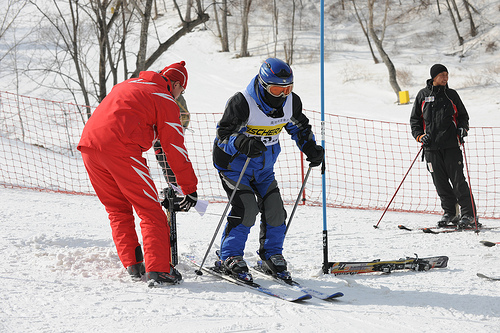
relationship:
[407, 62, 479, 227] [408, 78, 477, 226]
man wearing clothing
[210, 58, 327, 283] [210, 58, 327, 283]
man in man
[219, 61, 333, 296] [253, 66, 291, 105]
man in helmet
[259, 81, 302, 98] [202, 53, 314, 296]
goggles in man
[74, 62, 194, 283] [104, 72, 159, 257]
man in suit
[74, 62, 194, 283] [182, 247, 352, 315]
man on skis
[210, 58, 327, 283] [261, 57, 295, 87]
man wearing helmet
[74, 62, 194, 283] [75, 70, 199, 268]
man wearing outfit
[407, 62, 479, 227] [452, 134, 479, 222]
man holding ski pole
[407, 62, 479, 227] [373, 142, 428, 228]
man holding poles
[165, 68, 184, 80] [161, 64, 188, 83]
stripe on hat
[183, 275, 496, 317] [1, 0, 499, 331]
shadows on snow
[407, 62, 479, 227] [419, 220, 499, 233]
man wearing ski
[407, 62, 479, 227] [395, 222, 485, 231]
man wearing ski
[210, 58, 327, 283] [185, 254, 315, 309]
man wearing ski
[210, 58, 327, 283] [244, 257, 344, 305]
man wearing ski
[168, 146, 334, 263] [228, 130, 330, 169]
poles in skier's hand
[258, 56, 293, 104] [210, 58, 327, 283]
helmet on man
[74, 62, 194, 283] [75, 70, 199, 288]
man in outfit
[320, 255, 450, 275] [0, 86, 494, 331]
ski in snow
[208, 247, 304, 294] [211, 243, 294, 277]
boots on skier's feet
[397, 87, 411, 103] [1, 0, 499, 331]
object on snow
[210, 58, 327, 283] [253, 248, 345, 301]
man on ski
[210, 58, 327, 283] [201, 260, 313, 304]
man on ski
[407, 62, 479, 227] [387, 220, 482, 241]
man on skis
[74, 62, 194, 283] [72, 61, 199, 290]
man wearing gear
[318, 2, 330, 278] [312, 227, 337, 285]
blue pole with base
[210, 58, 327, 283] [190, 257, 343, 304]
man wearing skis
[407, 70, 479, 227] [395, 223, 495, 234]
man wearing skis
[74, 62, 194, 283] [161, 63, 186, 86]
man wearing hat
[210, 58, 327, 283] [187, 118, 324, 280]
man holding poles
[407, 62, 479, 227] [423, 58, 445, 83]
man wearing hat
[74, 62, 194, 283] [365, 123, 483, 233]
man holding poles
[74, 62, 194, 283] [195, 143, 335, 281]
man holding poles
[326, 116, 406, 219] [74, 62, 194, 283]
net behind man